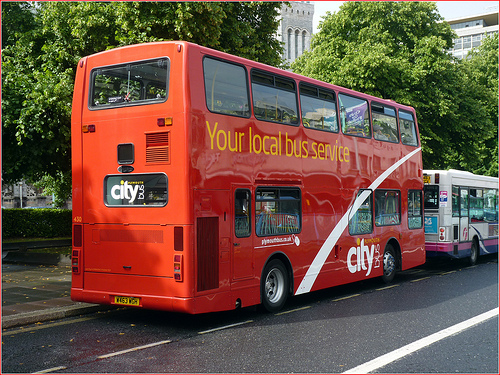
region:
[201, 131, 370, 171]
yellow writing on abus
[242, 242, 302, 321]
black tire of bus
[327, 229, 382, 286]
white writing on bus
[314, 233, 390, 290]
the word "city" on bus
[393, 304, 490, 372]
white line on street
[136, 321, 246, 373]
white lines on the street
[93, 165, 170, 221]
back window of bus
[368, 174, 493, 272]
two buses on the road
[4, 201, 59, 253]
green bush in background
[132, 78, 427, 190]
second level of bus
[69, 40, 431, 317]
Bright red double decker bus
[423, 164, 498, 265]
City bus with a pink stripe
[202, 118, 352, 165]
The words "Your local bus service"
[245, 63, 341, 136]
Two open bus windows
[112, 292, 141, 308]
Black and yellow license plate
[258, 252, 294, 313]
Tire and wheel of a bus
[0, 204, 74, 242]
Green hedgerow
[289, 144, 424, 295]
White curved large stripe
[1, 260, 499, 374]
Paved road with white lines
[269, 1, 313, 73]
Building with tall arches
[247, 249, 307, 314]
Black tire on a bus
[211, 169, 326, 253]
Window on a bus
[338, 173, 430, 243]
Windows on a bus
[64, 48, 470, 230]
Top of a bus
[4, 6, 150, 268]
Trees by a road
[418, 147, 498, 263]
White and pink bus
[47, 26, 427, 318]
Red bus on a road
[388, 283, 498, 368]
Gray pavement with white stripes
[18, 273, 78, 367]
Gray sidewalk by a road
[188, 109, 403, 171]
Yellow writing on a bus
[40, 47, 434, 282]
the bus is red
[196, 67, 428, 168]
the windows are shiny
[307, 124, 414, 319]
a white line on the side of the bus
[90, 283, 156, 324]
the license plate is yellow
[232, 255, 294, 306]
the tire is black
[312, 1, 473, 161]
the trees are bushy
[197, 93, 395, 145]
reflection of the clouds in the window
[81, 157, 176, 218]
the back window has writing on it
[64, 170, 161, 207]
the writing is white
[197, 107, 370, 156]
the letters are yellow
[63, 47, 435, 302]
A double decker bus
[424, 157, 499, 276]
a regular size bus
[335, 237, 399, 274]
The brand of the bus line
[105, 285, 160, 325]
the license plate of the bus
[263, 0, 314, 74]
A building showing between trees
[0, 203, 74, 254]
A shrub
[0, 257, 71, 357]
leaves on the sidewalk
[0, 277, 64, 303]
a drain on the sidewalk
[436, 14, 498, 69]
a large building showing behind the trees